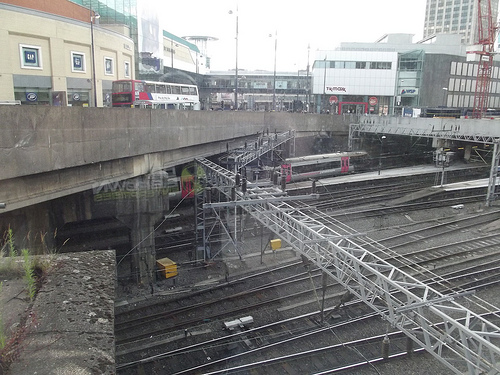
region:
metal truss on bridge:
[375, 260, 401, 283]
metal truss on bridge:
[436, 300, 466, 322]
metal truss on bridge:
[404, 279, 427, 296]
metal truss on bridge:
[348, 248, 364, 263]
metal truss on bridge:
[476, 323, 493, 338]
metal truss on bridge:
[411, 285, 435, 309]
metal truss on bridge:
[315, 219, 334, 239]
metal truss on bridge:
[295, 211, 307, 222]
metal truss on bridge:
[281, 204, 294, 216]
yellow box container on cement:
[159, 252, 184, 277]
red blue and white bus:
[106, 80, 210, 120]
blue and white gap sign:
[14, 43, 44, 70]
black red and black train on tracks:
[266, 148, 377, 181]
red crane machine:
[454, 0, 498, 121]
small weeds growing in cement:
[7, 234, 68, 291]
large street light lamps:
[220, 0, 245, 115]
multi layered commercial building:
[308, 25, 467, 125]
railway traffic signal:
[217, 120, 302, 170]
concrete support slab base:
[99, 160, 182, 295]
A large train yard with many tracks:
[65, 161, 490, 373]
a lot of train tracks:
[176, 182, 476, 374]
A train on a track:
[269, 149, 384, 178]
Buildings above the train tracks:
[17, 11, 499, 117]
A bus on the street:
[106, 71, 213, 118]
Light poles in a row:
[222, 5, 317, 114]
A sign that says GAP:
[19, 48, 46, 69]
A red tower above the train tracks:
[474, 40, 493, 120]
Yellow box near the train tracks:
[152, 253, 175, 280]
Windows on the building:
[316, 56, 393, 73]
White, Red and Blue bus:
[110, 68, 211, 111]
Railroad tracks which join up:
[110, 205, 497, 370]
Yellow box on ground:
[147, 252, 182, 279]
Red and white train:
[275, 140, 385, 180]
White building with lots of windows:
[297, 37, 417, 107]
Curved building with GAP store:
[0, 10, 146, 105]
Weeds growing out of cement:
[5, 208, 59, 320]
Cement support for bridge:
[112, 157, 168, 282]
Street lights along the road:
[215, 2, 322, 77]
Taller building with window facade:
[51, 0, 148, 42]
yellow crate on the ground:
[148, 253, 184, 285]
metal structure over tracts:
[271, 188, 493, 360]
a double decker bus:
[100, 68, 212, 120]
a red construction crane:
[453, 0, 499, 120]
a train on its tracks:
[258, 145, 419, 196]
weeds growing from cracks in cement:
[6, 238, 73, 333]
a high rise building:
[415, 2, 496, 44]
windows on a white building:
[313, 50, 403, 77]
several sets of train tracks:
[401, 216, 498, 260]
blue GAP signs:
[16, 32, 120, 82]